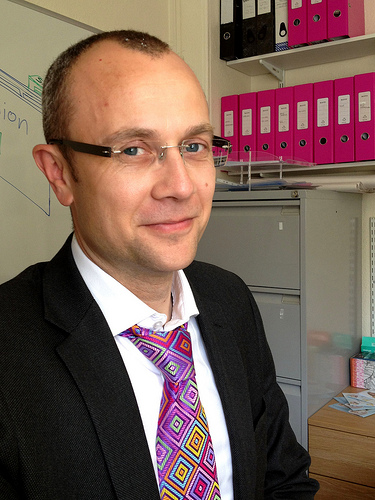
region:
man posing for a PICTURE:
[36, 27, 256, 375]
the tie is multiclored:
[141, 315, 234, 489]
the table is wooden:
[317, 411, 362, 492]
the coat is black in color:
[211, 260, 288, 406]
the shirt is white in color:
[132, 368, 159, 417]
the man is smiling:
[69, 106, 210, 292]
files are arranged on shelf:
[238, 33, 339, 124]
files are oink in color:
[247, 98, 358, 146]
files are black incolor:
[218, 13, 264, 48]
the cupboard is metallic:
[262, 211, 338, 331]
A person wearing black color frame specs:
[53, 123, 255, 171]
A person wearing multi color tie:
[132, 323, 220, 499]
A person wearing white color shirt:
[75, 245, 235, 498]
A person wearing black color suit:
[2, 8, 373, 498]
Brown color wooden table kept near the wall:
[312, 404, 373, 499]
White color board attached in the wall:
[2, 7, 47, 245]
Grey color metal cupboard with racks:
[235, 194, 328, 430]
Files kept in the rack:
[228, 96, 364, 165]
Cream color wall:
[124, 4, 185, 23]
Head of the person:
[19, 31, 242, 277]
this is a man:
[18, 11, 336, 378]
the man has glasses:
[69, 85, 232, 173]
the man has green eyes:
[109, 109, 254, 173]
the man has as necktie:
[94, 324, 217, 461]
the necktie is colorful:
[142, 340, 225, 484]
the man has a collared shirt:
[95, 279, 185, 363]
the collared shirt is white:
[83, 264, 203, 377]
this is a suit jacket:
[6, 252, 126, 470]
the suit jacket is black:
[33, 293, 150, 452]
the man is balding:
[55, 48, 160, 119]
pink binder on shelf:
[221, 94, 239, 161]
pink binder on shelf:
[237, 91, 256, 161]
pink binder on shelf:
[256, 88, 275, 161]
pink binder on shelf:
[273, 86, 293, 161]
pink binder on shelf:
[293, 83, 313, 161]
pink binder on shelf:
[313, 79, 333, 164]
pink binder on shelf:
[333, 76, 355, 162]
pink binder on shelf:
[353, 72, 373, 161]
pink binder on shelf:
[288, 0, 309, 50]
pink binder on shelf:
[305, 2, 326, 41]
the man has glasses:
[1, 38, 310, 499]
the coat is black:
[9, 264, 153, 499]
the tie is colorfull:
[146, 332, 233, 499]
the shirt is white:
[114, 294, 236, 499]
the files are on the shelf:
[227, 86, 371, 163]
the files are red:
[226, 89, 369, 159]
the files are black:
[222, 2, 272, 52]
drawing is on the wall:
[0, 70, 47, 208]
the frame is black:
[55, 130, 109, 158]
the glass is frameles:
[51, 121, 239, 176]